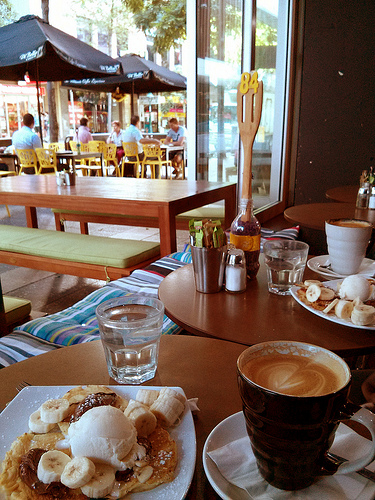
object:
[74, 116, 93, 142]
people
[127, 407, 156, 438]
banana slice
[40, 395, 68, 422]
banana slice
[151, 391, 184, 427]
banana slice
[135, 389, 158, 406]
banana slice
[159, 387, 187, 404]
banana slice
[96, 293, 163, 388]
glass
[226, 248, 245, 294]
salt shaker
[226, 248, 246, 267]
metal lid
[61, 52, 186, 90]
umbrella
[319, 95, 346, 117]
ground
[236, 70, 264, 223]
spatula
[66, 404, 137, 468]
ice cream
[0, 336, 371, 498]
table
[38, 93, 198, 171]
cloth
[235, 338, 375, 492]
coffee mug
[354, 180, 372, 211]
pepper shaker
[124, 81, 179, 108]
floor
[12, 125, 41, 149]
shirt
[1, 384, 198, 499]
plate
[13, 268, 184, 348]
cloth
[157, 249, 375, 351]
table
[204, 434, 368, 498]
cloth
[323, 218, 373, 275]
cup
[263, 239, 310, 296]
cup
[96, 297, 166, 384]
cup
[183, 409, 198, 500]
edge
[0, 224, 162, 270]
cushion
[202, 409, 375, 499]
dish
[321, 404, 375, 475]
handle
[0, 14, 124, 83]
black umbrellas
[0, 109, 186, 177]
dinning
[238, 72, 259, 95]
table number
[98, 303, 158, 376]
water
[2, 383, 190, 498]
dessert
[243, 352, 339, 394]
beverage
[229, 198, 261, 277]
jar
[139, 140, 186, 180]
table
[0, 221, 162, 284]
bench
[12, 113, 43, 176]
man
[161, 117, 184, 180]
person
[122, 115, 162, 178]
person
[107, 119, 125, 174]
person